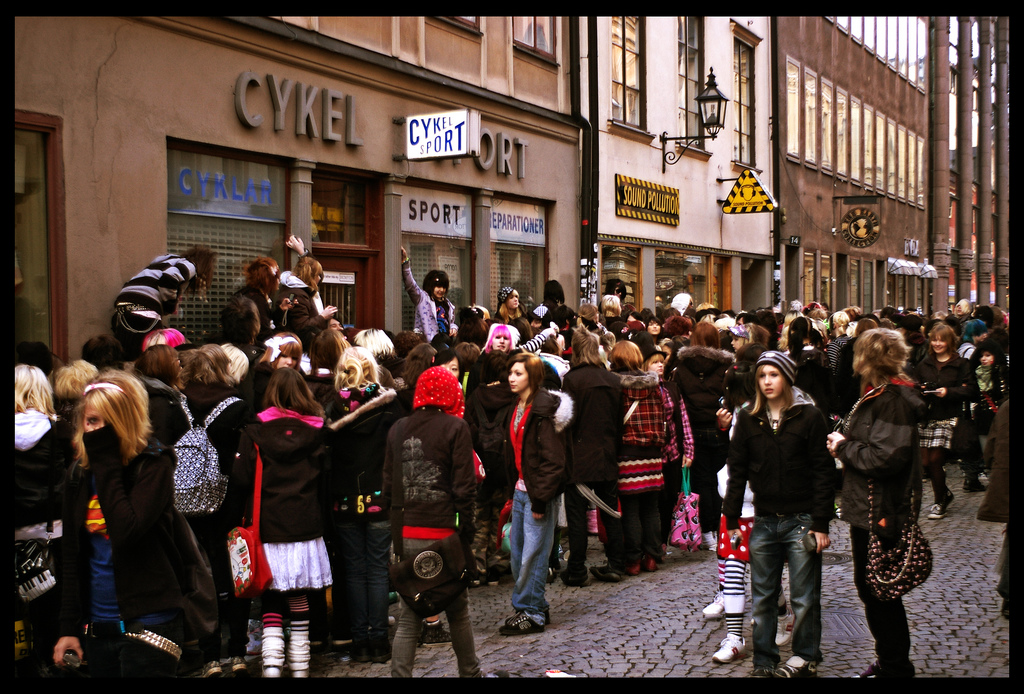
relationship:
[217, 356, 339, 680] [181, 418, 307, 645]
person holding on to bag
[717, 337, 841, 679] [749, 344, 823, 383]
person wearing a hat